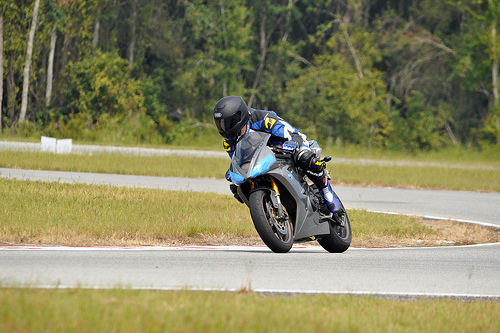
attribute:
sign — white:
[55, 135, 77, 158]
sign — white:
[36, 133, 60, 155]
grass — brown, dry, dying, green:
[1, 144, 497, 194]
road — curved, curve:
[0, 166, 499, 230]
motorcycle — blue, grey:
[222, 123, 358, 256]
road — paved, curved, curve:
[1, 235, 499, 302]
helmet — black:
[210, 91, 252, 141]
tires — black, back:
[311, 182, 356, 252]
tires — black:
[245, 186, 296, 254]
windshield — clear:
[229, 127, 274, 180]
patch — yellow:
[260, 116, 277, 133]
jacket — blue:
[227, 107, 308, 162]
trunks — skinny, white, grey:
[17, 0, 40, 122]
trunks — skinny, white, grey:
[44, 28, 57, 111]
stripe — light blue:
[220, 153, 279, 186]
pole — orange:
[270, 178, 282, 198]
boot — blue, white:
[314, 171, 341, 211]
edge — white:
[1, 239, 499, 258]